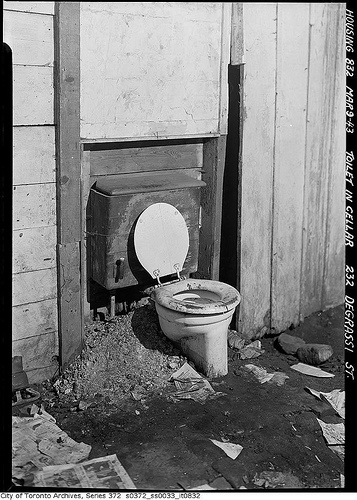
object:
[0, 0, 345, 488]
picture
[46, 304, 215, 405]
dirt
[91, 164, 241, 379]
toilet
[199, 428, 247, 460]
papers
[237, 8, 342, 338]
wall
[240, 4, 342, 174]
wood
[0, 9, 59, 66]
boards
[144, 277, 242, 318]
seat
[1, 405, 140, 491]
newspaper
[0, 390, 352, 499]
floor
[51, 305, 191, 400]
rocks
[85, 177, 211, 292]
tank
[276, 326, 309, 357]
stone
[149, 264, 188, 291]
hinge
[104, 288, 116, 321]
pipe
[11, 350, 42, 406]
ice skate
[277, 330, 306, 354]
another stone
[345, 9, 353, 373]
words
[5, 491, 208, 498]
writing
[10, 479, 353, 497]
bottom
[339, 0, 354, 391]
writing